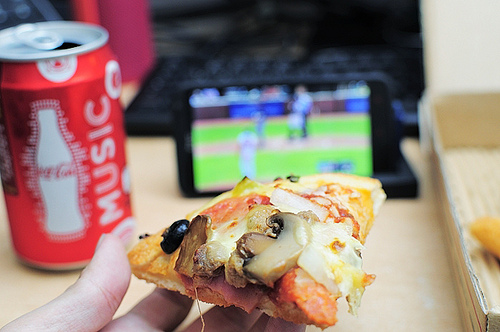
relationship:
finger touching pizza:
[0, 230, 131, 330] [120, 165, 394, 326]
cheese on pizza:
[313, 180, 373, 232] [126, 173, 373, 328]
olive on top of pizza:
[162, 221, 191, 249] [133, 157, 402, 308]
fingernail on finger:
[93, 231, 107, 255] [0, 230, 131, 330]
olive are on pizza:
[160, 219, 190, 254] [126, 173, 373, 328]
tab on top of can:
[16, 19, 66, 54] [1, 13, 136, 269]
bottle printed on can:
[27, 97, 93, 240] [1, 13, 136, 269]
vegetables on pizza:
[165, 182, 350, 317] [191, 189, 352, 281]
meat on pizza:
[193, 193, 336, 316] [191, 189, 352, 281]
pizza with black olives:
[132, 126, 358, 330] [154, 215, 210, 252]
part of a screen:
[233, 132, 261, 152] [185, 82, 376, 193]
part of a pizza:
[243, 210, 276, 259] [126, 173, 373, 328]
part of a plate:
[464, 141, 476, 169] [248, 161, 305, 229]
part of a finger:
[55, 294, 90, 318] [100, 286, 190, 330]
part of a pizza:
[273, 249, 292, 274] [135, 179, 410, 291]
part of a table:
[415, 279, 445, 326] [452, 267, 484, 307]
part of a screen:
[262, 120, 311, 153] [185, 82, 376, 193]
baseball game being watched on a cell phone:
[176, 77, 380, 190] [175, 72, 399, 198]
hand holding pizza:
[0, 221, 319, 328] [120, 165, 394, 326]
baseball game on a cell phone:
[176, 77, 380, 190] [166, 71, 418, 196]